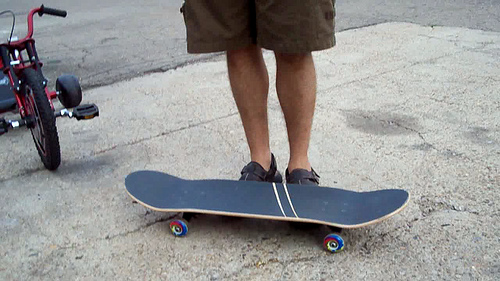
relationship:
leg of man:
[210, 40, 297, 158] [204, 2, 346, 183]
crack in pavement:
[374, 98, 454, 142] [332, 69, 474, 162]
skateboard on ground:
[113, 133, 440, 265] [185, 231, 294, 279]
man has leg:
[204, 2, 346, 183] [210, 40, 297, 158]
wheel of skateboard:
[165, 220, 197, 236] [113, 133, 440, 265]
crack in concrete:
[374, 98, 454, 142] [362, 93, 453, 157]